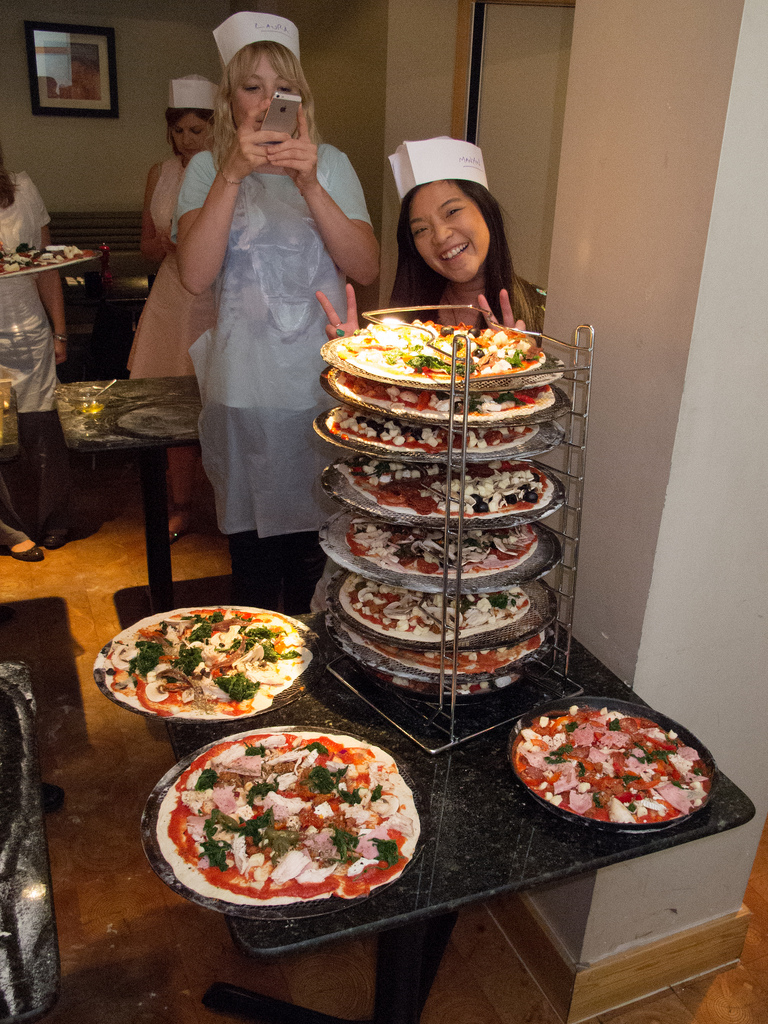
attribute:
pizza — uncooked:
[530, 681, 729, 841]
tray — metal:
[530, 681, 729, 841]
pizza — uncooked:
[335, 335, 557, 396]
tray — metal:
[335, 335, 550, 396]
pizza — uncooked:
[317, 373, 560, 438]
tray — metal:
[317, 373, 560, 438]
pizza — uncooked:
[323, 411, 556, 474]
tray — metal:
[323, 411, 556, 474]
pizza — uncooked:
[329, 466, 559, 526]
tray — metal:
[329, 466, 559, 526]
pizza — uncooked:
[333, 521, 568, 590]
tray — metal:
[333, 521, 568, 590]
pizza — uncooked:
[333, 578, 555, 654]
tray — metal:
[333, 578, 555, 654]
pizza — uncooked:
[365, 644, 598, 698]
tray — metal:
[365, 644, 598, 698]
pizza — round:
[184, 757, 397, 875]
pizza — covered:
[134, 736, 419, 892]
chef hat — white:
[384, 133, 499, 203]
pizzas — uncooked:
[313, 284, 642, 836]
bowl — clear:
[0, 651, 48, 847]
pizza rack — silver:
[355, 305, 567, 447]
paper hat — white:
[384, 132, 491, 204]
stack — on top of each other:
[318, 293, 573, 739]